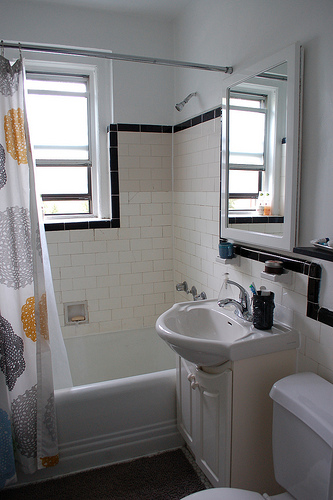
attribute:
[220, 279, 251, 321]
faucet — silver, metal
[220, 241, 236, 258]
cup — blue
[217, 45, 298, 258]
frame — white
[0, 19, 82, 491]
shower curtain — grey, orange, white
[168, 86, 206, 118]
shower head — silver, metal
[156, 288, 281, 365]
kitchen sink — white, ceramic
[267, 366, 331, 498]
toilet tank — ceramic, white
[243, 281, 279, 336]
toothbrush holder — black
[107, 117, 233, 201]
bathroom tiles — ivory, ceramic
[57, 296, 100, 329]
soap holder — ivory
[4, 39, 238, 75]
rod — silver, metal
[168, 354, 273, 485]
cabinet — white, wooden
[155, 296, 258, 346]
handwash — white, clean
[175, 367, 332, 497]
toilet — clean, white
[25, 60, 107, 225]
window — white, big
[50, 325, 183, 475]
tub — white, clean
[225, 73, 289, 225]
mirror — clean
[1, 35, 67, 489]
curtain — white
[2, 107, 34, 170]
circle — yellow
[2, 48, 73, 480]
curtain — white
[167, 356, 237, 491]
doors — little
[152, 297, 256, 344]
handwash — white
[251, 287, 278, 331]
can — black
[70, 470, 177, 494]
mat — black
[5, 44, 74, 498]
shower curtain — hanging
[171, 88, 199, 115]
shower — silver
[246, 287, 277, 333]
holder — black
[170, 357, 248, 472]
cabinet — white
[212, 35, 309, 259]
cabinet — white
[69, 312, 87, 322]
soap — orange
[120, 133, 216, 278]
wall — tiled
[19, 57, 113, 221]
window — closed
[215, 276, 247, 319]
faucet — silver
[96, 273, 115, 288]
tile — white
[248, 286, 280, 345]
cup — black